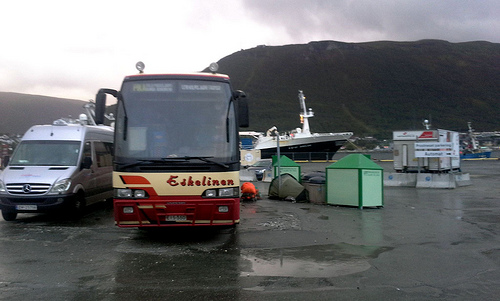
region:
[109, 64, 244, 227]
the front of a tour bus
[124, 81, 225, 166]
the windshield of a bus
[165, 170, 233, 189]
the logo of a bus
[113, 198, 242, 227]
the bumper of a bus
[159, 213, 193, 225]
the license plate of a bus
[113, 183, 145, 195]
the headlight of a bus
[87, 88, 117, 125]
the mirror of a bus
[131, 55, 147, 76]
the lights of a bus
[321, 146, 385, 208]
a small green shed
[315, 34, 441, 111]
a dark green mountain full of trees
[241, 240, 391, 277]
A puddle on the ground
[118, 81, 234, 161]
A window on the bus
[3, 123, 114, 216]
A silver van next to the bus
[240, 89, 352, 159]
A boat behind the bus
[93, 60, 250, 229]
A bus near a boat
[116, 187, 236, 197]
Headlights on the bus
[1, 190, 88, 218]
The front tires of the van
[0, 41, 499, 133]
Hills behind the boat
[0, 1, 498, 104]
A cloudy sky above the bus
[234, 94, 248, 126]
A mirror on the bus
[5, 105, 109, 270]
the van is silver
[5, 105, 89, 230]
the van is silver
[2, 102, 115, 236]
the van is silver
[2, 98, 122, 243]
the van is silver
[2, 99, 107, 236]
the van is silver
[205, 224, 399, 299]
a puddle of water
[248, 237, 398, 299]
a puddle of water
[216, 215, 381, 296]
a puddle of water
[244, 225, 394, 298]
a puddle of water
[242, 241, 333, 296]
a puddle of water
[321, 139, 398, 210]
the boxes are green in color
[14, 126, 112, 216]
the car is silvery in color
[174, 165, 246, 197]
words are written in red color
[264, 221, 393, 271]
the floor is wet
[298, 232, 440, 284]
floor is black in color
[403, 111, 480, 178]
the building in the middle of a construction field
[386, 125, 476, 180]
the building is white in color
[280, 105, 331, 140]
boat is white and black in color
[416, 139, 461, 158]
the p[osters are white in color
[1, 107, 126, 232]
This is a van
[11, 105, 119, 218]
This is a van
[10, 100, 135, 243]
This is a van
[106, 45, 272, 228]
This is a van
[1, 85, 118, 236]
This is a van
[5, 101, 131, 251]
This is a van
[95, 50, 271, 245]
This is a van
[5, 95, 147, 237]
This is a van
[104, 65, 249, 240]
red and tan bus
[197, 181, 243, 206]
white headlight on bus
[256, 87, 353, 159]
boat is black and white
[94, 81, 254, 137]
mirrors on the bus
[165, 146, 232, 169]
windshield wiper on the bus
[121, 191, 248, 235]
bus is red below the headlights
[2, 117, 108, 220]
van is silver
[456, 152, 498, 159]
boat is blue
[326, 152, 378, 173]
roof is green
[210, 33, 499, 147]
mountain behind the boats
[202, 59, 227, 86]
light on top of red bus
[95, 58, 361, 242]
white and black boat by bus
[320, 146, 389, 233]
green tent on parking lot